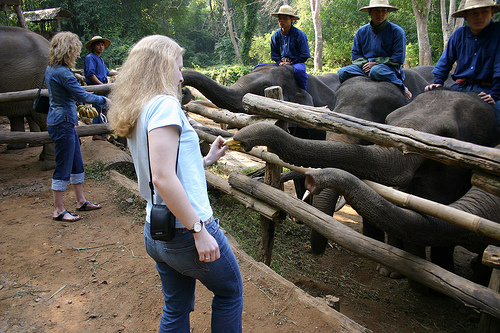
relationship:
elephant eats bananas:
[182, 63, 355, 97] [70, 98, 101, 125]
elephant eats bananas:
[221, 85, 500, 258] [70, 98, 101, 125]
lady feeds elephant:
[109, 34, 242, 331] [230, 88, 499, 299]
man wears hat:
[265, 5, 317, 80] [273, 3, 298, 15]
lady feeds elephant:
[109, 34, 242, 331] [178, 65, 340, 218]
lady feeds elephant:
[109, 34, 242, 331] [309, 61, 447, 256]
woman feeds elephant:
[38, 26, 120, 226] [231, 90, 498, 212]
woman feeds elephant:
[38, 26, 120, 226] [305, 166, 498, 312]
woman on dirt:
[38, 26, 120, 226] [6, 164, 140, 328]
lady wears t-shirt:
[109, 34, 242, 331] [123, 96, 214, 227]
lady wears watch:
[109, 34, 242, 331] [187, 217, 205, 239]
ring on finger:
[202, 252, 210, 264] [206, 247, 211, 262]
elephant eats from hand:
[235, 86, 496, 203] [203, 135, 226, 168]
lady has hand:
[109, 34, 242, 331] [203, 135, 226, 168]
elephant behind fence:
[235, 86, 496, 203] [188, 86, 499, 328]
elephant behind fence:
[183, 51, 320, 257] [188, 86, 499, 328]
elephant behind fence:
[241, 65, 426, 250] [188, 86, 499, 328]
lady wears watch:
[109, 34, 242, 331] [190, 217, 205, 234]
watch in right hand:
[190, 217, 205, 234] [193, 230, 225, 260]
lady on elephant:
[109, 34, 242, 331] [273, 60, 490, 237]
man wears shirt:
[253, 5, 315, 91] [281, 44, 293, 54]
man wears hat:
[253, 5, 315, 91] [284, 37, 291, 46]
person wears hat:
[424, 3, 499, 79] [452, 4, 496, 21]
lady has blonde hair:
[109, 34, 242, 331] [103, 31, 198, 138]